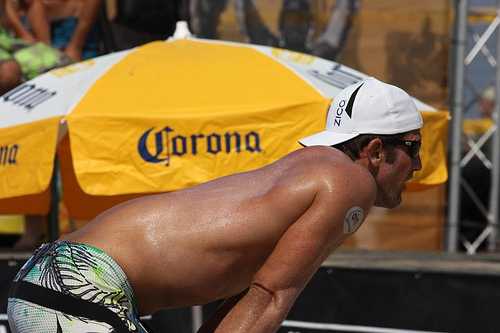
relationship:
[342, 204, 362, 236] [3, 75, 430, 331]
sticker on man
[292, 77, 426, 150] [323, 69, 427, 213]
cap on head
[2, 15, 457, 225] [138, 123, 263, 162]
umbrella with word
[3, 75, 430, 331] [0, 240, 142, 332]
man wearing shorts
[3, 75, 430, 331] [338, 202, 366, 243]
man has sticker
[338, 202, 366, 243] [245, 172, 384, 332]
sticker on arm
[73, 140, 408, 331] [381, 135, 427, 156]
man wearing sunglasses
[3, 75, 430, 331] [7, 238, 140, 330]
man wearing trunks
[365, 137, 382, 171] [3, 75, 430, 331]
ear of man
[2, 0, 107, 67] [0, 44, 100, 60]
people sitting at table